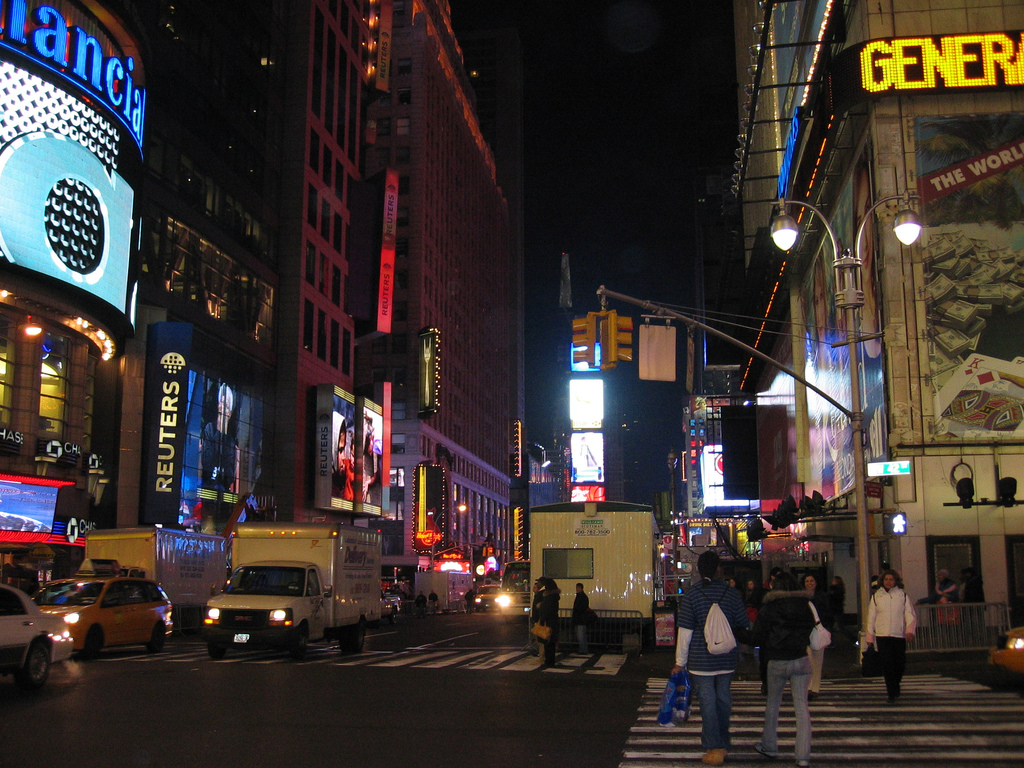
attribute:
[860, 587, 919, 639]
coat — white 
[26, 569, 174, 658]
car — yellow 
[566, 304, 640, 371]
signal — yellow 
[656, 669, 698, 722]
bag — blue 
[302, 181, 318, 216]
window — glass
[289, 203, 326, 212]
window — glass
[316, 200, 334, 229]
window — glass